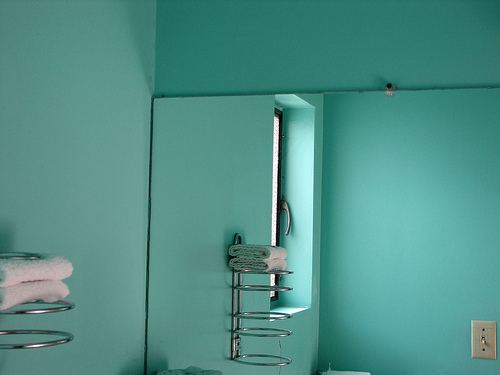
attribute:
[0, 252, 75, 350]
towel rack — metal, chrome, silver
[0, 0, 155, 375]
wall — turquoise, painted green, a section, painted, green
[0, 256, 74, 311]
towels — folded, white material, white, stacked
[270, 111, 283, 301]
window — closed, sunlit, rectangular, tall, a sliver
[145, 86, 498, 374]
mirror — large, wall mounted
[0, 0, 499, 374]
bathroom — teal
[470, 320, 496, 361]
light switch — white, cream, lined, off, turned off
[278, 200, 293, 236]
window handle — silver, metal